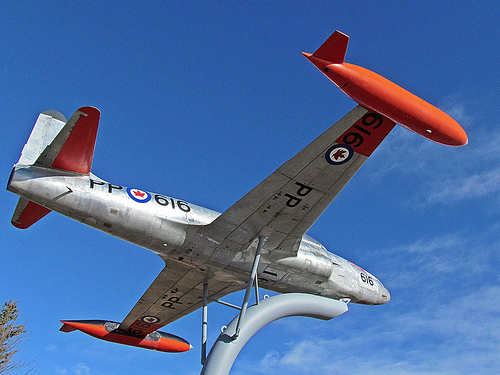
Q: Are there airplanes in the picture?
A: Yes, there is an airplane.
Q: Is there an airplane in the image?
A: Yes, there is an airplane.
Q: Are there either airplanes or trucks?
A: Yes, there is an airplane.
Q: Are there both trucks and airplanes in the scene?
A: No, there is an airplane but no trucks.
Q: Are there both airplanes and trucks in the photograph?
A: No, there is an airplane but no trucks.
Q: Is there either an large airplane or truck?
A: Yes, there is a large airplane.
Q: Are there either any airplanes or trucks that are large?
A: Yes, the airplane is large.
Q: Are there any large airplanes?
A: Yes, there is a large airplane.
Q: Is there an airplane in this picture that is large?
A: Yes, there is an airplane that is large.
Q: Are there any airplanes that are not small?
A: Yes, there is a large airplane.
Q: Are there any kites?
A: No, there are no kites.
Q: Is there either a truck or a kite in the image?
A: No, there are no kites or trucks.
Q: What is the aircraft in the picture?
A: The aircraft is an airplane.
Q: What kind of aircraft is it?
A: The aircraft is an airplane.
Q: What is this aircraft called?
A: This is an airplane.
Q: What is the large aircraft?
A: The aircraft is an airplane.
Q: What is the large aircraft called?
A: The aircraft is an airplane.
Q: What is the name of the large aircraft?
A: The aircraft is an airplane.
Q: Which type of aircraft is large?
A: The aircraft is an airplane.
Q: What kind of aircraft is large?
A: The aircraft is an airplane.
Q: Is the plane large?
A: Yes, the plane is large.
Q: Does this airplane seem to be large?
A: Yes, the airplane is large.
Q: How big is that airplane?
A: The airplane is large.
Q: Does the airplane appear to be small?
A: No, the airplane is large.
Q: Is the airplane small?
A: No, the airplane is large.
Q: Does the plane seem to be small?
A: No, the plane is large.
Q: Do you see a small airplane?
A: No, there is an airplane but it is large.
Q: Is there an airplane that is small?
A: No, there is an airplane but it is large.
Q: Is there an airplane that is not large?
A: No, there is an airplane but it is large.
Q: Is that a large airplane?
A: Yes, that is a large airplane.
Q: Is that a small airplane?
A: No, that is a large airplane.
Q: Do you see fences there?
A: No, there are no fences.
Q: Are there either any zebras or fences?
A: No, there are no fences or zebras.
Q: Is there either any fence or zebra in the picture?
A: No, there are no fences or zebras.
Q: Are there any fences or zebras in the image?
A: No, there are no fences or zebras.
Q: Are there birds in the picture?
A: No, there are no birds.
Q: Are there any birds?
A: No, there are no birds.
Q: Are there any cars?
A: No, there are no cars.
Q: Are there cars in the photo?
A: No, there are no cars.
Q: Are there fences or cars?
A: No, there are no cars or fences.